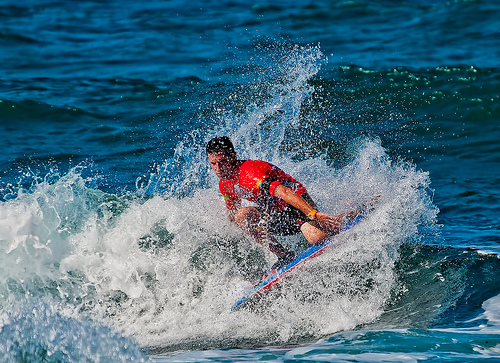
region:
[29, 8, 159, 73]
small ripples on surface of water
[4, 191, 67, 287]
wave covered in white sea foam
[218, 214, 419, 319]
blue and red surfboard covered in water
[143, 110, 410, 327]
man riding surfboard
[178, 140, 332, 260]
surfer in red and black wetsuit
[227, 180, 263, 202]
design on front of wet suit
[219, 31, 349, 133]
wave water splashing in air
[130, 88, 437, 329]
surfer covered in watre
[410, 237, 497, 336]
small wave forming on water surface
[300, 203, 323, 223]
orange plastic wristwatch on surfer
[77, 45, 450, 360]
a surfer in the ocean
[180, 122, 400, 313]
surfer is crouched on a surfboard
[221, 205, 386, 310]
surfboard is blue and red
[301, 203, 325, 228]
surfer a clock on a wrist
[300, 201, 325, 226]
clock is color orange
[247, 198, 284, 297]
a spiral thread above the surfboard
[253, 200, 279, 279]
the spiral thread is color white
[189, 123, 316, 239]
man has a red shirt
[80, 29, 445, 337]
splashes formed around surfer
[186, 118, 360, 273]
man wears a black short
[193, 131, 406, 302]
a man on a surf board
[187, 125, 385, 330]
a man surfing on a surfboard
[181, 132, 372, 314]
a man wearing a red wetsuit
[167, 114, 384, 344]
a man riding a wave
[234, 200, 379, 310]
a blue and red surf board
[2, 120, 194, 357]
a wave breaking on an ocean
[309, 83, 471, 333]
the wave of a surfboard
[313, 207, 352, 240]
the hand of a man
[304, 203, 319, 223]
an orange wristwatch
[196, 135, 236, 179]
the head of a man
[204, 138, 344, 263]
A man kneeling down in the water surfing.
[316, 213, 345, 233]
Left hand of a man surfing.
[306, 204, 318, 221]
Orange watch on a man's left wrist.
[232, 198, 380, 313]
Blue and red surfboard.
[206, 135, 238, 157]
Black hair on a surfer.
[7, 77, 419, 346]
Large white wave all around a man surfing.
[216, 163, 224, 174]
Nose on a mans face.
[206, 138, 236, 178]
Head of a man with black hair.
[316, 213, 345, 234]
Left hand of a man in the water.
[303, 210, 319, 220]
Orange watch on the wrist of a man.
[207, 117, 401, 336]
surfer kneeling on a surf board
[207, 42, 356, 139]
white spray coming up from the water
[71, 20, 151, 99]
blue water in the ocean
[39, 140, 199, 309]
giant wave crashing in the sea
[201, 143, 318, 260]
red shirt on a surfer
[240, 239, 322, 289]
blue top of a surf board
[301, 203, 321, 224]
yellow watch on a surfer's wrist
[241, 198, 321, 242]
black shorts on a surfer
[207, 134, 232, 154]
short hair on a surfer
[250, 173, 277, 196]
black stripe on a surfer's sleeve